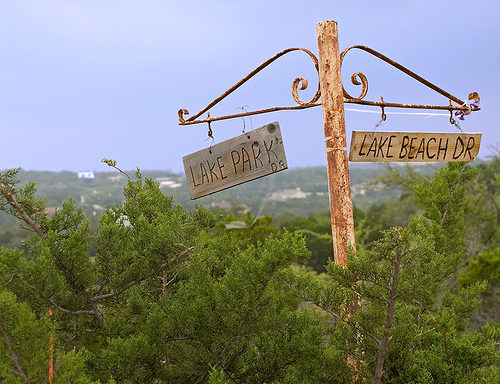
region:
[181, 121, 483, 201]
two wooden street signs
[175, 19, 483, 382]
a pole with two street signs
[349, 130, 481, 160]
Lake Beach Dr wooden sign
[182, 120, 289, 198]
Lake Park Dr wood sign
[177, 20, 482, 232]
a rusted pole holding two street signs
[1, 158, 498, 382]
evergreen tree branches in front of the pole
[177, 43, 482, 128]
rusted rods holding street signs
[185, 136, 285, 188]
the name of the street craved into the wood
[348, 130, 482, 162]
Lake Beach Dr craved on the sign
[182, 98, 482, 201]
two signs with wire tied to the rods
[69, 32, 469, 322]
wooden signs hanging down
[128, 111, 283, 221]
wooden sign with text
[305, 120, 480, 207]
long wooden sign with text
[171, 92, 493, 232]
branded wooden signs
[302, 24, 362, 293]
wooden post for signs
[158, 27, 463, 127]
metal sign holders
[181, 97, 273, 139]
material holding up signs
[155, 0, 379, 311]
rusted metal fixture for signs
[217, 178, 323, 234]
rocks in background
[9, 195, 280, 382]
green lush trees behind sign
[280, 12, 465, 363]
the post is rusty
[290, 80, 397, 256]
the post is rusty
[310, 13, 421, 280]
the post is rusty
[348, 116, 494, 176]
wooden sign on brown wooden post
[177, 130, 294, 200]
wooden sign on brown wooden post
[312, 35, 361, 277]
wooden post with signs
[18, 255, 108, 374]
brown tree with green leaves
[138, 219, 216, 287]
brown tree with green leaves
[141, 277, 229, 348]
brown tree with green leaves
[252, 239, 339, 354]
brown tree with green leaves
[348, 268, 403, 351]
brown tree with green leaves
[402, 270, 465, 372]
brown tree with green leaves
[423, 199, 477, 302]
brown tree with green leaves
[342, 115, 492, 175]
Sign made from wood.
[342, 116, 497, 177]
Printed letters on sign.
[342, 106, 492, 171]
The sign is homemade.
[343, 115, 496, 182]
The sign is rectangular.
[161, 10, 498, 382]
Sign post is white.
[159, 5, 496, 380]
Sign post is rusting.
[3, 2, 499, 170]
The sky is blue.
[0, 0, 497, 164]
The sky is clear.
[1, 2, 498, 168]
The sky is cloudless.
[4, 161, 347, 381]
A green pine tree.